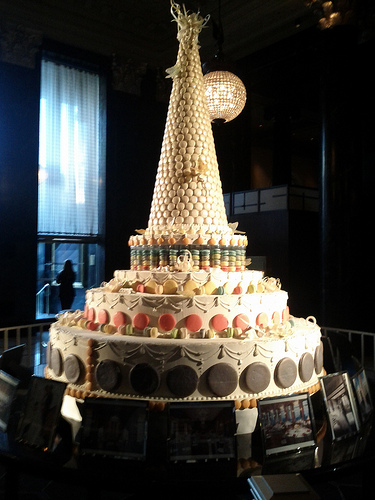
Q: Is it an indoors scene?
A: Yes, it is indoors.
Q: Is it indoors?
A: Yes, it is indoors.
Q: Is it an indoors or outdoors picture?
A: It is indoors.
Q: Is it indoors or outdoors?
A: It is indoors.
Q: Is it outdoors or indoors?
A: It is indoors.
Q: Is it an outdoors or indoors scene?
A: It is indoors.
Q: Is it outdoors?
A: No, it is indoors.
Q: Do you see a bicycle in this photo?
A: No, there are no bicycles.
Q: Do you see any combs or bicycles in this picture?
A: No, there are no bicycles or combs.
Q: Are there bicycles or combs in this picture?
A: No, there are no bicycles or combs.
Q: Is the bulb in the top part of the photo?
A: Yes, the bulb is in the top of the image.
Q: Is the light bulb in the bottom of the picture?
A: No, the light bulb is in the top of the image.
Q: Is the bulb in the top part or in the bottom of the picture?
A: The bulb is in the top of the image.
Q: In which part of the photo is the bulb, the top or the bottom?
A: The bulb is in the top of the image.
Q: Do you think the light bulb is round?
A: Yes, the light bulb is round.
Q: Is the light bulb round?
A: Yes, the light bulb is round.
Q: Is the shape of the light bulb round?
A: Yes, the light bulb is round.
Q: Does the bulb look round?
A: Yes, the bulb is round.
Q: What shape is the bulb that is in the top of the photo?
A: The light bulb is round.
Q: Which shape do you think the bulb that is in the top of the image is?
A: The light bulb is round.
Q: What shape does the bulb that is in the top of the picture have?
A: The light bulb has round shape.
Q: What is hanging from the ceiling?
A: The bulb is hanging from the ceiling.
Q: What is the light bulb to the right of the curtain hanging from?
A: The bulb is hanging from the ceiling.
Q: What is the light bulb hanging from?
A: The bulb is hanging from the ceiling.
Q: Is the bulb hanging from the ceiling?
A: Yes, the bulb is hanging from the ceiling.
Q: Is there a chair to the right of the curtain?
A: No, there is a light bulb to the right of the curtain.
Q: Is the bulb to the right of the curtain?
A: Yes, the bulb is to the right of the curtain.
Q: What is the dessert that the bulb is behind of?
A: The dessert is a cake.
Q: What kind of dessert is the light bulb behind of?
A: The bulb is behind the cake.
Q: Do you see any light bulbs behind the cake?
A: Yes, there is a light bulb behind the cake.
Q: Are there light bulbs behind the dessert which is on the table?
A: Yes, there is a light bulb behind the cake.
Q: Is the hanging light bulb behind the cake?
A: Yes, the bulb is behind the cake.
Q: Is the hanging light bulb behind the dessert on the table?
A: Yes, the bulb is behind the cake.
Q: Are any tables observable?
A: Yes, there is a table.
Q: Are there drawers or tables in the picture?
A: Yes, there is a table.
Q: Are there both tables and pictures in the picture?
A: Yes, there are both a table and a picture.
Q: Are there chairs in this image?
A: No, there are no chairs.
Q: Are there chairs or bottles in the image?
A: No, there are no chairs or bottles.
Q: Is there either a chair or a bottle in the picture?
A: No, there are no chairs or bottles.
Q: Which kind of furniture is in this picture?
A: The furniture is a table.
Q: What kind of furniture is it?
A: The piece of furniture is a table.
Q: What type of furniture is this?
A: This is a table.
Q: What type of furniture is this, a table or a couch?
A: This is a table.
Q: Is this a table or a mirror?
A: This is a table.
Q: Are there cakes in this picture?
A: Yes, there is a cake.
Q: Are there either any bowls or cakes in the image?
A: Yes, there is a cake.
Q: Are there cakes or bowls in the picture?
A: Yes, there is a cake.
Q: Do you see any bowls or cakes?
A: Yes, there is a cake.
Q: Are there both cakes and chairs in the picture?
A: No, there is a cake but no chairs.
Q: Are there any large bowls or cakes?
A: Yes, there is a large cake.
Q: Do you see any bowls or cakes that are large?
A: Yes, the cake is large.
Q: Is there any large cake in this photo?
A: Yes, there is a large cake.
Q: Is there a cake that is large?
A: Yes, there is a cake that is large.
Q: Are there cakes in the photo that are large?
A: Yes, there is a cake that is large.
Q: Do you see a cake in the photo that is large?
A: Yes, there is a cake that is large.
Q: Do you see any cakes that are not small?
A: Yes, there is a large cake.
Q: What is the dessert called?
A: The dessert is a cake.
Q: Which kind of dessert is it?
A: The dessert is a cake.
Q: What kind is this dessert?
A: This is a cake.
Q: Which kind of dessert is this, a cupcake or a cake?
A: This is a cake.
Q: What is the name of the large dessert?
A: The dessert is a cake.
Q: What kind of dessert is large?
A: The dessert is a cake.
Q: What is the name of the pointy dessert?
A: The dessert is a cake.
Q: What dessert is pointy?
A: The dessert is a cake.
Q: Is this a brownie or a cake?
A: This is a cake.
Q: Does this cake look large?
A: Yes, the cake is large.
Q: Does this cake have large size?
A: Yes, the cake is large.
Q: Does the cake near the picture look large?
A: Yes, the cake is large.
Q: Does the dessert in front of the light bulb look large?
A: Yes, the cake is large.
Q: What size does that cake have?
A: The cake has large size.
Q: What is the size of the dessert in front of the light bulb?
A: The cake is large.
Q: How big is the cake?
A: The cake is large.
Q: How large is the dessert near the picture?
A: The cake is large.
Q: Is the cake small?
A: No, the cake is large.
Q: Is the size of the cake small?
A: No, the cake is large.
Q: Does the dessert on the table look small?
A: No, the cake is large.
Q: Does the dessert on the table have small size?
A: No, the cake is large.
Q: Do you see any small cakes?
A: No, there is a cake but it is large.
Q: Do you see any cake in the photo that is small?
A: No, there is a cake but it is large.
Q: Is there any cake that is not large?
A: No, there is a cake but it is large.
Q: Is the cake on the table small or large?
A: The cake is large.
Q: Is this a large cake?
A: Yes, this is a large cake.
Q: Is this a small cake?
A: No, this is a large cake.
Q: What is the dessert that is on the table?
A: The dessert is a cake.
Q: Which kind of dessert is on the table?
A: The dessert is a cake.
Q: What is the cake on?
A: The cake is on the table.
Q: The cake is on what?
A: The cake is on the table.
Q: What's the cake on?
A: The cake is on the table.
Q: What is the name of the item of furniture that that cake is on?
A: The piece of furniture is a table.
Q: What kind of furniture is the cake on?
A: The cake is on the table.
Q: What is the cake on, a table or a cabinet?
A: The cake is on a table.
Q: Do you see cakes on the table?
A: Yes, there is a cake on the table.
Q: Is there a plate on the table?
A: No, there is a cake on the table.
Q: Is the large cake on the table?
A: Yes, the cake is on the table.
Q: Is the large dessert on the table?
A: Yes, the cake is on the table.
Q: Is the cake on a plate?
A: No, the cake is on the table.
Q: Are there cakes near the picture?
A: Yes, there is a cake near the picture.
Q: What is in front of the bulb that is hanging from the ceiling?
A: The cake is in front of the light bulb.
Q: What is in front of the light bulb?
A: The cake is in front of the light bulb.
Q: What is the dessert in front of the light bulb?
A: The dessert is a cake.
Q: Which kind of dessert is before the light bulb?
A: The dessert is a cake.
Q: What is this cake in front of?
A: The cake is in front of the bulb.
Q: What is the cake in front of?
A: The cake is in front of the bulb.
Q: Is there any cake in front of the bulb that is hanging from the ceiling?
A: Yes, there is a cake in front of the bulb.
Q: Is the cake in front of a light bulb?
A: Yes, the cake is in front of a light bulb.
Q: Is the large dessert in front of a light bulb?
A: Yes, the cake is in front of a light bulb.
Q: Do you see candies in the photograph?
A: Yes, there are candies.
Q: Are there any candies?
A: Yes, there are candies.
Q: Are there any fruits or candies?
A: Yes, there are candies.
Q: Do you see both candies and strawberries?
A: No, there are candies but no strawberries.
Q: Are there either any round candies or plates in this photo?
A: Yes, there are round candies.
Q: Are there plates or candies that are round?
A: Yes, the candies are round.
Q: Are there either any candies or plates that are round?
A: Yes, the candies are round.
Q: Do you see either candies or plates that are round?
A: Yes, the candies are round.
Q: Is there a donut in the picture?
A: No, there are no donuts.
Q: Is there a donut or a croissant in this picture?
A: No, there are no donuts or croissants.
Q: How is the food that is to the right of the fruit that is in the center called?
A: The food is candies.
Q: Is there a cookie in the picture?
A: Yes, there are cookies.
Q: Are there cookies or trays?
A: Yes, there are cookies.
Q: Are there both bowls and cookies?
A: No, there are cookies but no bowls.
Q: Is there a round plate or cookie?
A: Yes, there are round cookies.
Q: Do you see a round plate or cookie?
A: Yes, there are round cookies.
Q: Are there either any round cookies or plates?
A: Yes, there are round cookies.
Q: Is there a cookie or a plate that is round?
A: Yes, the cookies are round.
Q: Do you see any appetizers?
A: No, there are no appetizers.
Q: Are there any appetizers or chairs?
A: No, there are no appetizers or chairs.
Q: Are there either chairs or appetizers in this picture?
A: No, there are no appetizers or chairs.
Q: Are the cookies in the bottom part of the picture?
A: Yes, the cookies are in the bottom of the image.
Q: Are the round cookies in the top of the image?
A: No, the cookies are in the bottom of the image.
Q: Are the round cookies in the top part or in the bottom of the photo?
A: The cookies are in the bottom of the image.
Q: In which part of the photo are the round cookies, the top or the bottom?
A: The cookies are in the bottom of the image.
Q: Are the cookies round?
A: Yes, the cookies are round.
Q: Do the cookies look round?
A: Yes, the cookies are round.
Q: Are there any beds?
A: No, there are no beds.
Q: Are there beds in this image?
A: No, there are no beds.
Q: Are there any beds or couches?
A: No, there are no beds or couches.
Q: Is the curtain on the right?
A: No, the curtain is on the left of the image.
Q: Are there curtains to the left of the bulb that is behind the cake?
A: Yes, there is a curtain to the left of the light bulb.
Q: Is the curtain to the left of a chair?
A: No, the curtain is to the left of the bulb.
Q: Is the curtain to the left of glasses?
A: No, the curtain is to the left of the candies.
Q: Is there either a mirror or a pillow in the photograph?
A: No, there are no mirrors or pillows.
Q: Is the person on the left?
A: Yes, the person is on the left of the image.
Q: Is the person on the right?
A: No, the person is on the left of the image.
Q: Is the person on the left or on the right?
A: The person is on the left of the image.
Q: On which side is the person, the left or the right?
A: The person is on the left of the image.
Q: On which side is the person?
A: The person is on the left of the image.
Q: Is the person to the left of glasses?
A: No, the person is to the left of the candies.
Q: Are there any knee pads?
A: No, there are no knee pads.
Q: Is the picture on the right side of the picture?
A: Yes, the picture is on the right of the image.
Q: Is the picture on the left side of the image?
A: No, the picture is on the right of the image.